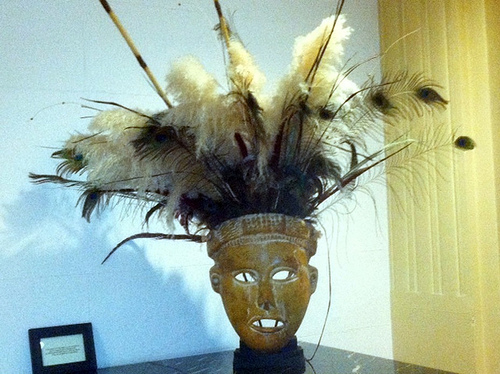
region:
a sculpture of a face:
[198, 211, 330, 356]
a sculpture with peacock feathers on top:
[22, 1, 478, 345]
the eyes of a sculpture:
[223, 261, 310, 285]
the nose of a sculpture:
[256, 286, 278, 308]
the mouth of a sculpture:
[242, 311, 290, 333]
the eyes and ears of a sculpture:
[207, 265, 318, 289]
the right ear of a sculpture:
[208, 260, 222, 295]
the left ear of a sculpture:
[305, 260, 320, 291]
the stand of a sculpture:
[228, 339, 309, 372]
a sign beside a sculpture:
[20, 321, 102, 370]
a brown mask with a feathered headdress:
[25, 0, 476, 352]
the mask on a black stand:
[202, 210, 317, 370]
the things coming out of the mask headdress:
[25, 0, 472, 265]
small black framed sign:
[25, 320, 102, 370]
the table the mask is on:
[91, 340, 466, 370]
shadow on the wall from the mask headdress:
[2, 180, 217, 370]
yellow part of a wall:
[375, 0, 495, 370]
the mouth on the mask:
[245, 310, 290, 330]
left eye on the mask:
[227, 265, 257, 285]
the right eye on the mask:
[271, 266, 298, 282]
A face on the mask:
[207, 215, 314, 342]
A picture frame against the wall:
[27, 321, 92, 367]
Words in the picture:
[45, 340, 82, 355]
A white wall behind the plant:
[0, 2, 392, 367]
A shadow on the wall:
[0, 186, 227, 366]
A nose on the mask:
[252, 281, 272, 306]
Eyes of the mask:
[230, 265, 296, 282]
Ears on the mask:
[201, 268, 318, 291]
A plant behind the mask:
[32, 3, 469, 328]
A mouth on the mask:
[247, 318, 284, 328]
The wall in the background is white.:
[30, 225, 87, 292]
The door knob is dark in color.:
[453, 136, 472, 148]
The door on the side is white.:
[401, 186, 481, 263]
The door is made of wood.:
[396, 191, 490, 256]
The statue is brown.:
[196, 223, 339, 345]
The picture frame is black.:
[24, 317, 105, 372]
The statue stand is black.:
[226, 344, 310, 370]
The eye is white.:
[270, 266, 310, 283]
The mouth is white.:
[246, 317, 287, 334]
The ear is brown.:
[201, 267, 223, 295]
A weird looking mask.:
[205, 215, 320, 352]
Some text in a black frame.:
[26, 320, 100, 372]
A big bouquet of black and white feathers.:
[25, 0, 478, 264]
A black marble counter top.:
[97, 342, 455, 372]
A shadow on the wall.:
[1, 182, 228, 372]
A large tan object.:
[377, 2, 498, 373]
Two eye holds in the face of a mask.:
[230, 264, 297, 289]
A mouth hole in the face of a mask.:
[247, 315, 287, 338]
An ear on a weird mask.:
[208, 263, 223, 295]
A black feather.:
[97, 230, 207, 266]